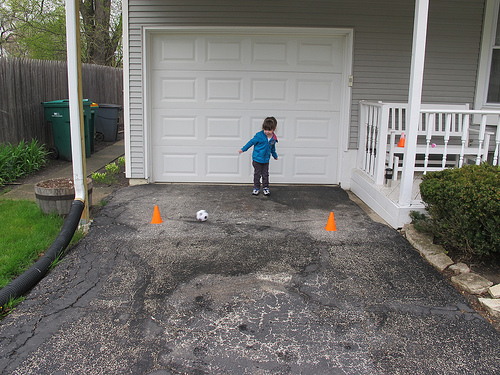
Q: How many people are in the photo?
A: One.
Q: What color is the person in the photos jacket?
A: Blue.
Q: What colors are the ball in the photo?
A: Black and white.